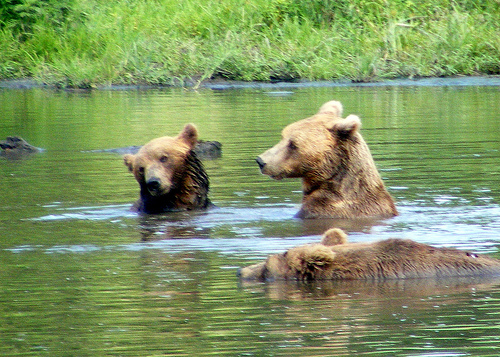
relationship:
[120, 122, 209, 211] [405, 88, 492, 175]
bear swimming in river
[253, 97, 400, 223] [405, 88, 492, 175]
bear swimming in river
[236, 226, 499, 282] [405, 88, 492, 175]
bear swimming in river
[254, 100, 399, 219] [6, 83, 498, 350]
bear standing in water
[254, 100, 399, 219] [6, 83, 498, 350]
bear in water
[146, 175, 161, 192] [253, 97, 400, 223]
nose of bear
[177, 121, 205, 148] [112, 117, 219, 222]
ear of bear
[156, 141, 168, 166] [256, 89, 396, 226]
eye of bear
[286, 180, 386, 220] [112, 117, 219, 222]
shoulder of bear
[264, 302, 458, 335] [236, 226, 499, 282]
reflection of bear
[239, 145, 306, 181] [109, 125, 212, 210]
mouth of bear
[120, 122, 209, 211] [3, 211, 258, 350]
bear in lake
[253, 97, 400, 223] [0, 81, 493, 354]
bear in lake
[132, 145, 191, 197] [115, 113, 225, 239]
face of bear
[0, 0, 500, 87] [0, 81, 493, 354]
shrubbery next to lake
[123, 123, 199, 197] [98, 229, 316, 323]
head in water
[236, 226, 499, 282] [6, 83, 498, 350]
bear lying in water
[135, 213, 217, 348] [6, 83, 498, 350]
reflection on water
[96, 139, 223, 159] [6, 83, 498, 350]
rock in water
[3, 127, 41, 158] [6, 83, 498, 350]
rock in water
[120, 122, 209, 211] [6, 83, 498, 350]
bear swimming in water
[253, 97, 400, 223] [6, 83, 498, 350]
bear swimming in water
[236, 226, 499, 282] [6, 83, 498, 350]
bear swimming in water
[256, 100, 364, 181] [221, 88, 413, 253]
head on bear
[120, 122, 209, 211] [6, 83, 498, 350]
bear in water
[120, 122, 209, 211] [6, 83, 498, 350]
bear playing in water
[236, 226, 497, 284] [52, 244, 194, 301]
bear playing in water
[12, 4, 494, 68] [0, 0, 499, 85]
grass on bank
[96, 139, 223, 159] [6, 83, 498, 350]
rock protruding from water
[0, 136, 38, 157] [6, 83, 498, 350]
rock protruding from water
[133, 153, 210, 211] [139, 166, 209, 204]
fur on neck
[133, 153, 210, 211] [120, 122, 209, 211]
fur on bear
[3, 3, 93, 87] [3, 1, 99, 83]
leaves on tree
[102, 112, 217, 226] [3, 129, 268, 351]
bear in river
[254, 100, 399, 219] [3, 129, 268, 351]
bear in river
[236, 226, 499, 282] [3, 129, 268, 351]
bear in river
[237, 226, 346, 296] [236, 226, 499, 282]
head on bear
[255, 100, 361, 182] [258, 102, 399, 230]
head on bear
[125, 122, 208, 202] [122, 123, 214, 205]
head on bear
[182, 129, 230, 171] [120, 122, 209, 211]
rock behind bear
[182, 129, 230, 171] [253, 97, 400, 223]
rock behind bear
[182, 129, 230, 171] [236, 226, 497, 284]
rock behind bear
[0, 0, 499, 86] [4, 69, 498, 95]
bank along river bank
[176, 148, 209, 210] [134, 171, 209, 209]
spot on neck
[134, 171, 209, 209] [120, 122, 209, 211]
neck on bear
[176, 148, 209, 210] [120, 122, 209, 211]
spot on bear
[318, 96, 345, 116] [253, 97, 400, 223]
ears on bear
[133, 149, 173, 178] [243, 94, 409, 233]
eyes on bear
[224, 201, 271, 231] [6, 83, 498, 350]
sunlight on water